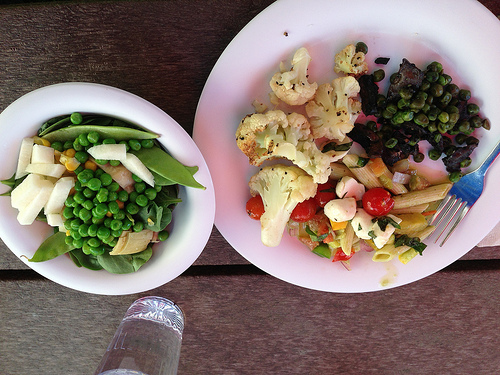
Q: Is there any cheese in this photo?
A: Yes, there is cheese.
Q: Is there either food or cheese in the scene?
A: Yes, there is cheese.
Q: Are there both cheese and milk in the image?
A: No, there is cheese but no milk.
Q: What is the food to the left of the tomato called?
A: The food is cheese.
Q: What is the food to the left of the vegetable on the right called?
A: The food is cheese.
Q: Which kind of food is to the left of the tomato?
A: The food is cheese.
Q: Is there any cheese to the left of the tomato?
A: Yes, there is cheese to the left of the tomato.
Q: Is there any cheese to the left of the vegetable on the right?
A: Yes, there is cheese to the left of the tomato.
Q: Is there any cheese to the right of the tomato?
A: No, the cheese is to the left of the tomato.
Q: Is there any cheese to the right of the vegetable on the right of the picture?
A: No, the cheese is to the left of the tomato.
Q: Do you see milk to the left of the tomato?
A: No, there is cheese to the left of the tomato.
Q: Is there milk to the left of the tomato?
A: No, there is cheese to the left of the tomato.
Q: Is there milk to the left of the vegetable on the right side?
A: No, there is cheese to the left of the tomato.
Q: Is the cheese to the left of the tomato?
A: Yes, the cheese is to the left of the tomato.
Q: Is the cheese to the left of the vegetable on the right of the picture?
A: Yes, the cheese is to the left of the tomato.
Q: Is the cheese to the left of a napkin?
A: No, the cheese is to the left of the tomato.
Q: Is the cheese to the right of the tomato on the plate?
A: No, the cheese is to the left of the tomato.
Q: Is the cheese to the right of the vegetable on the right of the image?
A: No, the cheese is to the left of the tomato.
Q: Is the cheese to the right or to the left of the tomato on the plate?
A: The cheese is to the left of the tomato.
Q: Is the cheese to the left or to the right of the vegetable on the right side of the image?
A: The cheese is to the left of the tomato.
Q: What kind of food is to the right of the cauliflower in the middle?
A: The food is cheese.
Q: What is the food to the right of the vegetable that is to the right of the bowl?
A: The food is cheese.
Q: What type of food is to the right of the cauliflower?
A: The food is cheese.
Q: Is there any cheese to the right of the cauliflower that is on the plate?
A: Yes, there is cheese to the right of the cauliflower.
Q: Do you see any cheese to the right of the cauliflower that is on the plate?
A: Yes, there is cheese to the right of the cauliflower.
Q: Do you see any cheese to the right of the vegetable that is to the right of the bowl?
A: Yes, there is cheese to the right of the cauliflower.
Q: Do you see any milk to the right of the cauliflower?
A: No, there is cheese to the right of the cauliflower.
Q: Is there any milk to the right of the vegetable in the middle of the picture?
A: No, there is cheese to the right of the cauliflower.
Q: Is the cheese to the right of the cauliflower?
A: Yes, the cheese is to the right of the cauliflower.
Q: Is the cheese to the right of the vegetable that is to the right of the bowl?
A: Yes, the cheese is to the right of the cauliflower.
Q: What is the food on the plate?
A: The food is cheese.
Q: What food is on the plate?
A: The food is cheese.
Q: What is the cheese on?
A: The cheese is on the plate.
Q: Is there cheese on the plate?
A: Yes, there is cheese on the plate.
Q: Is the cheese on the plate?
A: Yes, the cheese is on the plate.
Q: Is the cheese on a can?
A: No, the cheese is on the plate.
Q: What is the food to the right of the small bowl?
A: The food is cheese.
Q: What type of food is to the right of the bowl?
A: The food is cheese.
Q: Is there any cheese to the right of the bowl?
A: Yes, there is cheese to the right of the bowl.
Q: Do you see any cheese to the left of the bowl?
A: No, the cheese is to the right of the bowl.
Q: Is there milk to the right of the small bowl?
A: No, there is cheese to the right of the bowl.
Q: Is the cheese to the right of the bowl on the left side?
A: Yes, the cheese is to the right of the bowl.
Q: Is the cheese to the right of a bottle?
A: No, the cheese is to the right of the bowl.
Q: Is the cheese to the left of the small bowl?
A: No, the cheese is to the right of the bowl.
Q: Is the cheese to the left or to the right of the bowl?
A: The cheese is to the right of the bowl.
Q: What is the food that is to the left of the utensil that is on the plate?
A: The food is cheese.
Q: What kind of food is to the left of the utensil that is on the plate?
A: The food is cheese.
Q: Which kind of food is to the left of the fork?
A: The food is cheese.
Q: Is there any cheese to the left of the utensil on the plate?
A: Yes, there is cheese to the left of the fork.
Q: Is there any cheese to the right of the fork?
A: No, the cheese is to the left of the fork.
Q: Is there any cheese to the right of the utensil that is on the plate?
A: No, the cheese is to the left of the fork.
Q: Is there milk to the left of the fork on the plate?
A: No, there is cheese to the left of the fork.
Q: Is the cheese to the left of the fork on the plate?
A: Yes, the cheese is to the left of the fork.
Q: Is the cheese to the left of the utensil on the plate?
A: Yes, the cheese is to the left of the fork.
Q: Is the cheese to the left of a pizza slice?
A: No, the cheese is to the left of the fork.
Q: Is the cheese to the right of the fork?
A: No, the cheese is to the left of the fork.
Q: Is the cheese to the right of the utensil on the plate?
A: No, the cheese is to the left of the fork.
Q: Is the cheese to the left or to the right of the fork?
A: The cheese is to the left of the fork.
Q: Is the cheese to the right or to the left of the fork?
A: The cheese is to the left of the fork.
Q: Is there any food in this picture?
A: Yes, there is food.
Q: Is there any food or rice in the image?
A: Yes, there is food.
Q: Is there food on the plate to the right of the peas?
A: Yes, there is food on the plate.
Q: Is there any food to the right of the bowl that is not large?
A: Yes, there is food to the right of the bowl.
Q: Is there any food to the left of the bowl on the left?
A: No, the food is to the right of the bowl.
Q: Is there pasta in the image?
A: Yes, there is pasta.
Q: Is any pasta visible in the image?
A: Yes, there is pasta.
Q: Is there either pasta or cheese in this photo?
A: Yes, there is pasta.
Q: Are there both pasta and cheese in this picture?
A: Yes, there are both pasta and cheese.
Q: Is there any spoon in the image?
A: No, there are no spoons.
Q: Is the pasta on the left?
A: No, the pasta is on the right of the image.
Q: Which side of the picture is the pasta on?
A: The pasta is on the right of the image.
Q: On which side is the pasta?
A: The pasta is on the right of the image.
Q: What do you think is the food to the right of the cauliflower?
A: The food is pasta.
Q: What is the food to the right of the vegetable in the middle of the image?
A: The food is pasta.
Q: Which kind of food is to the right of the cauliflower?
A: The food is pasta.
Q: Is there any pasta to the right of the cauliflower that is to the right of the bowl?
A: Yes, there is pasta to the right of the cauliflower.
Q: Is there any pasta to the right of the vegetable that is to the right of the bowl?
A: Yes, there is pasta to the right of the cauliflower.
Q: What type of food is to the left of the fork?
A: The food is pasta.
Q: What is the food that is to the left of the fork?
A: The food is pasta.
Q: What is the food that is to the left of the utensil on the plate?
A: The food is pasta.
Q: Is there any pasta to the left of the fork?
A: Yes, there is pasta to the left of the fork.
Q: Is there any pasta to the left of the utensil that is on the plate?
A: Yes, there is pasta to the left of the fork.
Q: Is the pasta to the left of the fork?
A: Yes, the pasta is to the left of the fork.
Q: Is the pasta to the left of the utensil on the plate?
A: Yes, the pasta is to the left of the fork.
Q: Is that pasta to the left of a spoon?
A: No, the pasta is to the left of the fork.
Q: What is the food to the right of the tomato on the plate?
A: The food is pasta.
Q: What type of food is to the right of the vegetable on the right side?
A: The food is pasta.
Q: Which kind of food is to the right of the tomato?
A: The food is pasta.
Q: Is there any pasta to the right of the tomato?
A: Yes, there is pasta to the right of the tomato.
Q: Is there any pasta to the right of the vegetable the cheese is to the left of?
A: Yes, there is pasta to the right of the tomato.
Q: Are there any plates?
A: Yes, there is a plate.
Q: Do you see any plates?
A: Yes, there is a plate.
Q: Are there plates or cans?
A: Yes, there is a plate.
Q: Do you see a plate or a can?
A: Yes, there is a plate.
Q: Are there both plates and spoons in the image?
A: No, there is a plate but no spoons.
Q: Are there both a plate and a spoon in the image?
A: No, there is a plate but no spoons.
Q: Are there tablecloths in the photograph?
A: No, there are no tablecloths.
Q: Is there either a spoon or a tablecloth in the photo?
A: No, there are no tablecloths or spoons.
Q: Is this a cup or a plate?
A: This is a plate.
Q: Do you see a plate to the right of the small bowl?
A: Yes, there is a plate to the right of the bowl.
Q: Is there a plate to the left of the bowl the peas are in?
A: No, the plate is to the right of the bowl.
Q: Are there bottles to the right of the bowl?
A: No, there is a plate to the right of the bowl.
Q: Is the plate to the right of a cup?
A: No, the plate is to the right of the bowl.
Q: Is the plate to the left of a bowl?
A: No, the plate is to the right of a bowl.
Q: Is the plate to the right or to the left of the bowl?
A: The plate is to the right of the bowl.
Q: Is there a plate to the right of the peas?
A: Yes, there is a plate to the right of the peas.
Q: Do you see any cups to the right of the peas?
A: No, there is a plate to the right of the peas.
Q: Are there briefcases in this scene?
A: No, there are no briefcases.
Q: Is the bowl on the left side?
A: Yes, the bowl is on the left of the image.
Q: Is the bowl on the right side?
A: No, the bowl is on the left of the image.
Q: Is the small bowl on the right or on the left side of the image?
A: The bowl is on the left of the image.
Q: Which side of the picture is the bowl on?
A: The bowl is on the left of the image.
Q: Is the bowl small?
A: Yes, the bowl is small.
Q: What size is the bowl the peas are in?
A: The bowl is small.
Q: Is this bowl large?
A: No, the bowl is small.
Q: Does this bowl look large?
A: No, the bowl is small.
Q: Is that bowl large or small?
A: The bowl is small.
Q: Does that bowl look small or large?
A: The bowl is small.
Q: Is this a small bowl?
A: Yes, this is a small bowl.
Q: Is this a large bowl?
A: No, this is a small bowl.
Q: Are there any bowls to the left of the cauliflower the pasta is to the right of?
A: Yes, there is a bowl to the left of the cauliflower.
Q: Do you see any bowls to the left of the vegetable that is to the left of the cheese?
A: Yes, there is a bowl to the left of the cauliflower.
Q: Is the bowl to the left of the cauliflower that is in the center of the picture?
A: Yes, the bowl is to the left of the cauliflower.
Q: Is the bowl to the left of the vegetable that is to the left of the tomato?
A: Yes, the bowl is to the left of the cauliflower.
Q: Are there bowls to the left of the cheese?
A: Yes, there is a bowl to the left of the cheese.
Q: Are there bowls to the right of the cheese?
A: No, the bowl is to the left of the cheese.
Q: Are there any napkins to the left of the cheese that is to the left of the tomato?
A: No, there is a bowl to the left of the cheese.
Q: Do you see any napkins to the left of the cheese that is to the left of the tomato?
A: No, there is a bowl to the left of the cheese.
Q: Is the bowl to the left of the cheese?
A: Yes, the bowl is to the left of the cheese.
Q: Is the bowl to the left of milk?
A: No, the bowl is to the left of the cheese.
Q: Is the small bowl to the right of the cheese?
A: No, the bowl is to the left of the cheese.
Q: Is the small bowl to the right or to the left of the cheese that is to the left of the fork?
A: The bowl is to the left of the cheese.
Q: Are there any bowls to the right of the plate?
A: No, the bowl is to the left of the plate.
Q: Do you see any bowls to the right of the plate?
A: No, the bowl is to the left of the plate.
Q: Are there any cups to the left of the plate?
A: No, there is a bowl to the left of the plate.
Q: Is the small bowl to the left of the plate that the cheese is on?
A: Yes, the bowl is to the left of the plate.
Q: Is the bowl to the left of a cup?
A: No, the bowl is to the left of the plate.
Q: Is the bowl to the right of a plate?
A: No, the bowl is to the left of a plate.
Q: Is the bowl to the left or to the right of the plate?
A: The bowl is to the left of the plate.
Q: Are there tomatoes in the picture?
A: Yes, there is a tomato.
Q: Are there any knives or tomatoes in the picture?
A: Yes, there is a tomato.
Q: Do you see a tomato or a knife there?
A: Yes, there is a tomato.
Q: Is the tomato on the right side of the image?
A: Yes, the tomato is on the right of the image.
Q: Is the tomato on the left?
A: No, the tomato is on the right of the image.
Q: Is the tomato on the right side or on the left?
A: The tomato is on the right of the image.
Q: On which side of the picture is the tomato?
A: The tomato is on the right of the image.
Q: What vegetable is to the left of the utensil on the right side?
A: The vegetable is a tomato.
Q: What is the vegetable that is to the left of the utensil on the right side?
A: The vegetable is a tomato.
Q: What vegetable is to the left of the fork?
A: The vegetable is a tomato.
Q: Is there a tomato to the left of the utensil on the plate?
A: Yes, there is a tomato to the left of the fork.